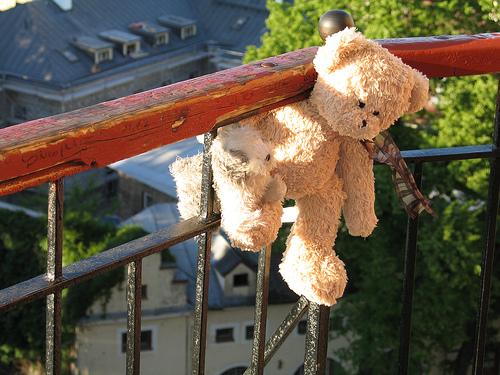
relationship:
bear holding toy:
[184, 40, 438, 310] [169, 130, 286, 217]